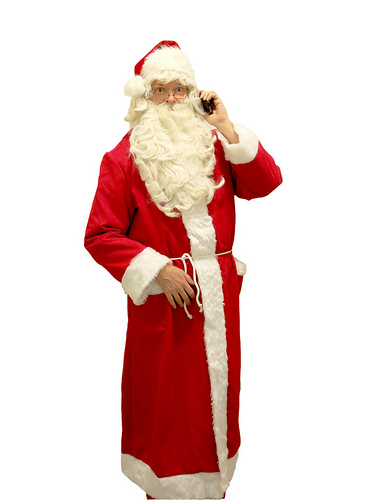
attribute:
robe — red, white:
[86, 123, 283, 498]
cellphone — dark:
[196, 95, 216, 119]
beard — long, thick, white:
[123, 93, 223, 217]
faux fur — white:
[198, 267, 231, 478]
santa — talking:
[81, 38, 284, 499]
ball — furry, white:
[124, 75, 145, 95]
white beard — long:
[129, 99, 224, 219]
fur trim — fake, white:
[121, 247, 172, 306]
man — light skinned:
[77, 30, 291, 498]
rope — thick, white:
[151, 245, 244, 322]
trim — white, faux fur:
[180, 200, 229, 491]